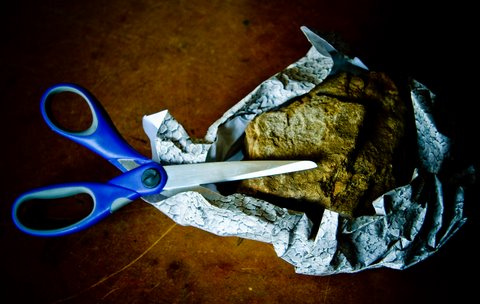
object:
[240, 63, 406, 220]
brown rock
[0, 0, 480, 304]
floor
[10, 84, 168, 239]
blue handles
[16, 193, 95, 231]
hole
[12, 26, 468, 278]
rock scissors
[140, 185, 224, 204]
blade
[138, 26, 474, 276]
paper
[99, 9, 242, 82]
area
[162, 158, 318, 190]
blades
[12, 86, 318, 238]
scissors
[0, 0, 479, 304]
table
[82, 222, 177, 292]
scratch